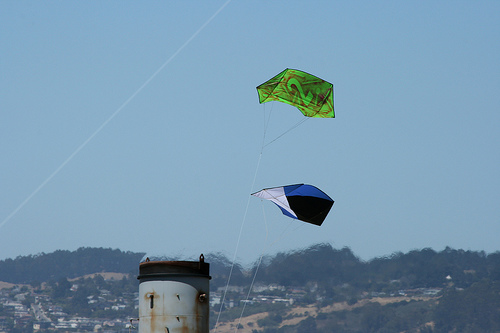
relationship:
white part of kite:
[249, 184, 300, 226] [248, 169, 345, 234]